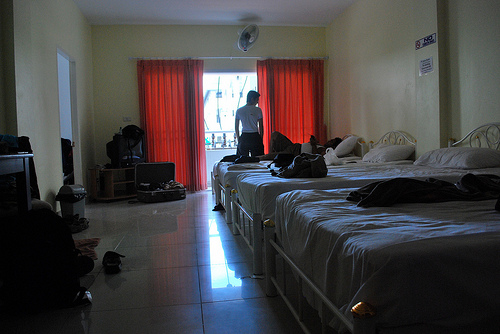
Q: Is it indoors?
A: Yes, it is indoors.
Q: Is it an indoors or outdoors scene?
A: It is indoors.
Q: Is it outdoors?
A: No, it is indoors.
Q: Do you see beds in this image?
A: Yes, there is a bed.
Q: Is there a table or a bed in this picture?
A: Yes, there is a bed.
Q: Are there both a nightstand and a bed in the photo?
A: No, there is a bed but no nightstands.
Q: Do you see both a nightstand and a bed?
A: No, there is a bed but no nightstands.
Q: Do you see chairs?
A: No, there are no chairs.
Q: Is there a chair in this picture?
A: No, there are no chairs.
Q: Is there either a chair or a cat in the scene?
A: No, there are no chairs or cats.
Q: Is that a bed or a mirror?
A: That is a bed.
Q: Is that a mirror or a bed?
A: That is a bed.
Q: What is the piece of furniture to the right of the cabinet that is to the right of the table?
A: The piece of furniture is a bed.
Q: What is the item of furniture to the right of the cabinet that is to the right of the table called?
A: The piece of furniture is a bed.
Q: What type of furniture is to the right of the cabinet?
A: The piece of furniture is a bed.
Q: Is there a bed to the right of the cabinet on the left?
A: Yes, there is a bed to the right of the cabinet.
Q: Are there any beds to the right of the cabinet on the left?
A: Yes, there is a bed to the right of the cabinet.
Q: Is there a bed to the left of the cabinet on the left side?
A: No, the bed is to the right of the cabinet.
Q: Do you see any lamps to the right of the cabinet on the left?
A: No, there is a bed to the right of the cabinet.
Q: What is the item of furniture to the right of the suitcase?
A: The piece of furniture is a bed.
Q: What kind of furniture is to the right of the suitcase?
A: The piece of furniture is a bed.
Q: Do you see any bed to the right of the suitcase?
A: Yes, there is a bed to the right of the suitcase.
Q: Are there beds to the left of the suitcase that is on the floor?
A: No, the bed is to the right of the suitcase.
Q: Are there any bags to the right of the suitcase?
A: No, there is a bed to the right of the suitcase.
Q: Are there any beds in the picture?
A: Yes, there is a bed.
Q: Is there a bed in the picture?
A: Yes, there is a bed.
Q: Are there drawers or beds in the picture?
A: Yes, there is a bed.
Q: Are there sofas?
A: No, there are no sofas.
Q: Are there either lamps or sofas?
A: No, there are no sofas or lamps.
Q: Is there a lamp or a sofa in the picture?
A: No, there are no sofas or lamps.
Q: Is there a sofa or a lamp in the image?
A: No, there are no sofas or lamps.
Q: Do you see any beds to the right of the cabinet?
A: Yes, there is a bed to the right of the cabinet.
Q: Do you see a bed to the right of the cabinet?
A: Yes, there is a bed to the right of the cabinet.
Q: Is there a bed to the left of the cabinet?
A: No, the bed is to the right of the cabinet.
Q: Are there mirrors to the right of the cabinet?
A: No, there is a bed to the right of the cabinet.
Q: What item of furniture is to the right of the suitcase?
A: The piece of furniture is a bed.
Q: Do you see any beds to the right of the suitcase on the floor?
A: Yes, there is a bed to the right of the suitcase.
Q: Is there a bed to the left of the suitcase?
A: No, the bed is to the right of the suitcase.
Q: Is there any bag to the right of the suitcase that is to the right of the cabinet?
A: No, there is a bed to the right of the suitcase.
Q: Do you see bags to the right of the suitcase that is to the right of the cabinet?
A: No, there is a bed to the right of the suitcase.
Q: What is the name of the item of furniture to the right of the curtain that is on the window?
A: The piece of furniture is a bed.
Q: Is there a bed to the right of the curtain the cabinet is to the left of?
A: Yes, there is a bed to the right of the curtain.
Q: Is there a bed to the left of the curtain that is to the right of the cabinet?
A: No, the bed is to the right of the curtain.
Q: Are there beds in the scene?
A: Yes, there is a bed.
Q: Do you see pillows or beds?
A: Yes, there is a bed.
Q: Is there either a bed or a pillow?
A: Yes, there is a bed.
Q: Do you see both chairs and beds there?
A: No, there is a bed but no chairs.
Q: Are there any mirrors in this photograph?
A: No, there are no mirrors.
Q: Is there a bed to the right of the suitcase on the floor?
A: Yes, there is a bed to the right of the suitcase.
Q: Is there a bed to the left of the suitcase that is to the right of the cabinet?
A: No, the bed is to the right of the suitcase.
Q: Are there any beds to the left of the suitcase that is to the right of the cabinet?
A: No, the bed is to the right of the suitcase.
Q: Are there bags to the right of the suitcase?
A: No, there is a bed to the right of the suitcase.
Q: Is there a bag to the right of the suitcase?
A: No, there is a bed to the right of the suitcase.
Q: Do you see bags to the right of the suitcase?
A: No, there is a bed to the right of the suitcase.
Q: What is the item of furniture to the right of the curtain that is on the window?
A: The piece of furniture is a bed.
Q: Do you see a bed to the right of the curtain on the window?
A: Yes, there is a bed to the right of the curtain.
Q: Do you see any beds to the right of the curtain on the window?
A: Yes, there is a bed to the right of the curtain.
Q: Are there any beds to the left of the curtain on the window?
A: No, the bed is to the right of the curtain.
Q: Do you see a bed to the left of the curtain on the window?
A: No, the bed is to the right of the curtain.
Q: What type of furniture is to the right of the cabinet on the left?
A: The piece of furniture is a bed.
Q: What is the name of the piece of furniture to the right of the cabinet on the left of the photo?
A: The piece of furniture is a bed.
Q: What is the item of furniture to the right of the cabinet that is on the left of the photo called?
A: The piece of furniture is a bed.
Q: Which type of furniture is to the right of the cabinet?
A: The piece of furniture is a bed.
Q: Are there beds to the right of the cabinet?
A: Yes, there is a bed to the right of the cabinet.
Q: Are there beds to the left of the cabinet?
A: No, the bed is to the right of the cabinet.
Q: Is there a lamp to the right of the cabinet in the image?
A: No, there is a bed to the right of the cabinet.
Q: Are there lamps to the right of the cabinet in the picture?
A: No, there is a bed to the right of the cabinet.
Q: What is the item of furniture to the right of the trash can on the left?
A: The piece of furniture is a bed.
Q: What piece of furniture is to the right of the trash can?
A: The piece of furniture is a bed.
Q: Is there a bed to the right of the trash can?
A: Yes, there is a bed to the right of the trash can.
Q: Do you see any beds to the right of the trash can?
A: Yes, there is a bed to the right of the trash can.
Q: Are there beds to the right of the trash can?
A: Yes, there is a bed to the right of the trash can.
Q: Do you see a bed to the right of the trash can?
A: Yes, there is a bed to the right of the trash can.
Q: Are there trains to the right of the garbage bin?
A: No, there is a bed to the right of the garbage bin.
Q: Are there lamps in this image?
A: No, there are no lamps.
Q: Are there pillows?
A: Yes, there is a pillow.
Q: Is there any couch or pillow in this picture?
A: Yes, there is a pillow.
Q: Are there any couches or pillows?
A: Yes, there is a pillow.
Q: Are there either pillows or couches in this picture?
A: Yes, there is a pillow.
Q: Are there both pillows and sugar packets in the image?
A: No, there is a pillow but no sugar packets.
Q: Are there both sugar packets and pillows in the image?
A: No, there is a pillow but no sugar packets.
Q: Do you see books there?
A: No, there are no books.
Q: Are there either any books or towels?
A: No, there are no books or towels.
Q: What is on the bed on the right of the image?
A: The pillow is on the bed.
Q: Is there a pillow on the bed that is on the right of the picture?
A: Yes, there is a pillow on the bed.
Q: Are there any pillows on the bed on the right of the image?
A: Yes, there is a pillow on the bed.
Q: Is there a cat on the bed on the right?
A: No, there is a pillow on the bed.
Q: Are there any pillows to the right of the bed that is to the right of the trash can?
A: Yes, there is a pillow to the right of the bed.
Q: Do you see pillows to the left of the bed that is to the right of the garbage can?
A: No, the pillow is to the right of the bed.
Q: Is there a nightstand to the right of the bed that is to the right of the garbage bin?
A: No, there is a pillow to the right of the bed.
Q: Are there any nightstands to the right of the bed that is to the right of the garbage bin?
A: No, there is a pillow to the right of the bed.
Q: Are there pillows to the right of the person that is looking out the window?
A: Yes, there is a pillow to the right of the person.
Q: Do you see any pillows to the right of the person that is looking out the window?
A: Yes, there is a pillow to the right of the person.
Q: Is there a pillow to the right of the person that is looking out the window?
A: Yes, there is a pillow to the right of the person.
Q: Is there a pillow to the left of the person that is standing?
A: No, the pillow is to the right of the person.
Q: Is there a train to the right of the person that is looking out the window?
A: No, there is a pillow to the right of the person.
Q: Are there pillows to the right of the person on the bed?
A: Yes, there is a pillow to the right of the man.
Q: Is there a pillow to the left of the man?
A: No, the pillow is to the right of the man.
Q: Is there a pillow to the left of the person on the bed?
A: No, the pillow is to the right of the man.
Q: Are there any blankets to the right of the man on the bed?
A: No, there is a pillow to the right of the man.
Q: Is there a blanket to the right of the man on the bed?
A: No, there is a pillow to the right of the man.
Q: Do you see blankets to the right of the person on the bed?
A: No, there is a pillow to the right of the man.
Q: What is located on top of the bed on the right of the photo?
A: The pillow is on top of the bed.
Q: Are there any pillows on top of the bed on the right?
A: Yes, there is a pillow on top of the bed.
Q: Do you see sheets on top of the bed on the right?
A: No, there is a pillow on top of the bed.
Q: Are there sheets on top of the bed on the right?
A: No, there is a pillow on top of the bed.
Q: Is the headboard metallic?
A: Yes, the headboard is metallic.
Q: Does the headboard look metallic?
A: Yes, the headboard is metallic.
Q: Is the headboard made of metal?
A: Yes, the headboard is made of metal.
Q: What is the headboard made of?
A: The headboard is made of metal.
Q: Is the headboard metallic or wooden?
A: The headboard is metallic.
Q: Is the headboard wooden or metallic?
A: The headboard is metallic.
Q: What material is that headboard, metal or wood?
A: The headboard is made of metal.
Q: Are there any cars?
A: No, there are no cars.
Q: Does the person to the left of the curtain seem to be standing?
A: Yes, the person is standing.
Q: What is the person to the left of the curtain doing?
A: The person is standing.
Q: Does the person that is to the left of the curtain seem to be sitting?
A: No, the person is standing.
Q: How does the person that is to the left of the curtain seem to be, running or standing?
A: The person is standing.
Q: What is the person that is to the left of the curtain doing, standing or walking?
A: The person is standing.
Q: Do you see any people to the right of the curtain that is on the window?
A: Yes, there is a person to the right of the curtain.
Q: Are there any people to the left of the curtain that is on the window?
A: No, the person is to the right of the curtain.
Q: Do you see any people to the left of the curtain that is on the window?
A: No, the person is to the right of the curtain.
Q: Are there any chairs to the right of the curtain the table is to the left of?
A: No, there is a person to the right of the curtain.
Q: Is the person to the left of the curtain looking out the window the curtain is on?
A: Yes, the person is looking out the window.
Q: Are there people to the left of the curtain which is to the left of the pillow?
A: Yes, there is a person to the left of the curtain.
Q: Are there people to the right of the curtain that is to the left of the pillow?
A: No, the person is to the left of the curtain.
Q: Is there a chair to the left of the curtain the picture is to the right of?
A: No, there is a person to the left of the curtain.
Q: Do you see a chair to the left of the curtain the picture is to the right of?
A: No, there is a person to the left of the curtain.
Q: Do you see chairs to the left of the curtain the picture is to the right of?
A: No, there is a person to the left of the curtain.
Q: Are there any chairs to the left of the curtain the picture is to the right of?
A: No, there is a person to the left of the curtain.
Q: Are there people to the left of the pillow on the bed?
A: Yes, there is a person to the left of the pillow.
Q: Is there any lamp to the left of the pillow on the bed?
A: No, there is a person to the left of the pillow.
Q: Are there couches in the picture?
A: No, there are no couches.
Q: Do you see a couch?
A: No, there are no couches.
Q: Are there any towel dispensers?
A: No, there are no towel dispensers.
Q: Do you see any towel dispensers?
A: No, there are no towel dispensers.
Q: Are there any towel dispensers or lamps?
A: No, there are no towel dispensers or lamps.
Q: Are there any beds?
A: Yes, there is a bed.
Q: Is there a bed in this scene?
A: Yes, there is a bed.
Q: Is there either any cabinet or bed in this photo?
A: Yes, there is a bed.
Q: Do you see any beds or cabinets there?
A: Yes, there is a bed.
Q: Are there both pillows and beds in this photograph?
A: Yes, there are both a bed and pillows.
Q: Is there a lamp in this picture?
A: No, there are no lamps.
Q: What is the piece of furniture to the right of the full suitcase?
A: The piece of furniture is a bed.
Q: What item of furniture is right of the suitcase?
A: The piece of furniture is a bed.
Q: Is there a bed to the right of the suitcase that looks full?
A: Yes, there is a bed to the right of the suitcase.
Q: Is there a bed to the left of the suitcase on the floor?
A: No, the bed is to the right of the suitcase.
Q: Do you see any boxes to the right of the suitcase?
A: No, there is a bed to the right of the suitcase.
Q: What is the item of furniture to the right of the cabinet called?
A: The piece of furniture is a bed.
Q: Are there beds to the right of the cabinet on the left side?
A: Yes, there is a bed to the right of the cabinet.